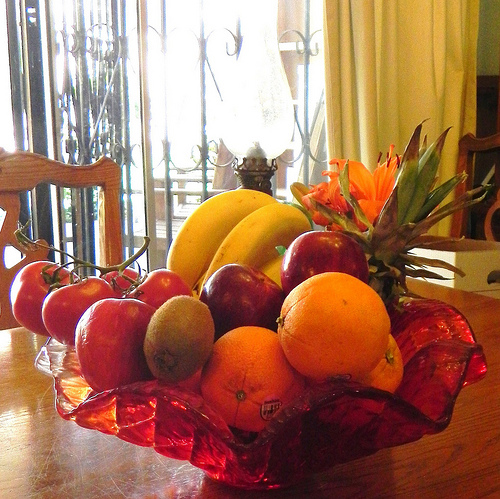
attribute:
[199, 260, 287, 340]
apple — red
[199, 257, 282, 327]
apple — red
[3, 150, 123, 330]
chair — wood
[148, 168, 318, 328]
bananas — yellow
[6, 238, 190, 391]
tomatoes — red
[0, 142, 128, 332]
chair — wooden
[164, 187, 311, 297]
bananas — yellow 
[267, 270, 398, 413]
orange — fruit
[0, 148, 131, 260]
chair — brown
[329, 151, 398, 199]
flower — orange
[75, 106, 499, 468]
table — wooden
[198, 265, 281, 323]
apple — red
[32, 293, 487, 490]
bowl — red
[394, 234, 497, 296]
box — white, cardboard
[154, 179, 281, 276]
banana — yellow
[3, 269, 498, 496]
table — brown